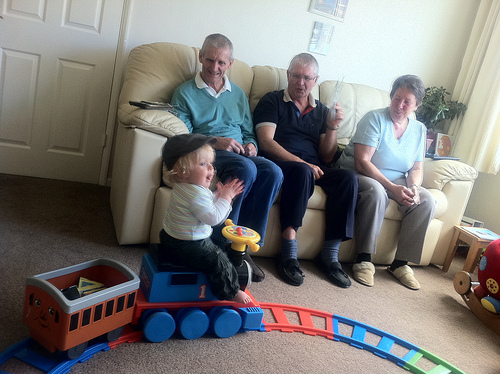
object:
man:
[169, 33, 284, 282]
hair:
[201, 33, 234, 62]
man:
[254, 53, 359, 288]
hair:
[287, 53, 319, 77]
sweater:
[169, 78, 259, 152]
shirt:
[194, 71, 232, 99]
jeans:
[212, 147, 284, 250]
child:
[160, 133, 251, 304]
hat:
[160, 133, 217, 171]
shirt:
[161, 183, 232, 241]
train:
[20, 249, 264, 365]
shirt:
[253, 88, 333, 167]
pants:
[354, 174, 436, 265]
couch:
[109, 42, 478, 273]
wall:
[357, 1, 459, 56]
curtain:
[440, 0, 500, 176]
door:
[0, 0, 127, 186]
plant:
[413, 85, 467, 132]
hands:
[216, 178, 244, 198]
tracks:
[0, 299, 467, 374]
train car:
[22, 256, 140, 359]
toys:
[59, 275, 105, 301]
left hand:
[327, 102, 346, 127]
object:
[330, 82, 341, 120]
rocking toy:
[452, 234, 500, 337]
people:
[335, 73, 435, 290]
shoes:
[277, 254, 353, 288]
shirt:
[335, 107, 427, 182]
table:
[440, 225, 499, 276]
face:
[27, 292, 60, 331]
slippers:
[386, 264, 421, 290]